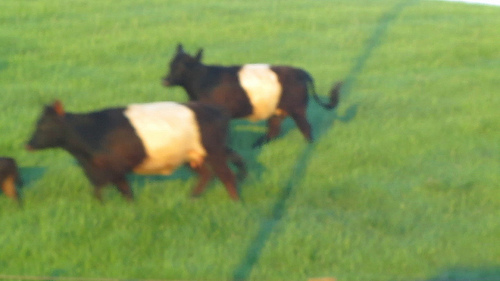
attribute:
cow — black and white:
[160, 42, 340, 146]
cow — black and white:
[4, 62, 458, 250]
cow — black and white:
[142, 29, 353, 168]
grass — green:
[406, 105, 458, 159]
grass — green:
[49, 202, 452, 272]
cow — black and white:
[156, 37, 344, 151]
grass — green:
[315, 144, 495, 264]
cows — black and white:
[21, 42, 341, 209]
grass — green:
[4, 0, 497, 280]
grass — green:
[294, 160, 498, 280]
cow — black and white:
[27, 98, 247, 205]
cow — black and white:
[21, 85, 174, 177]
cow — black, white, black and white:
[13, 93, 246, 200]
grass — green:
[366, 28, 482, 233]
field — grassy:
[2, 1, 498, 279]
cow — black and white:
[25, 86, 249, 209]